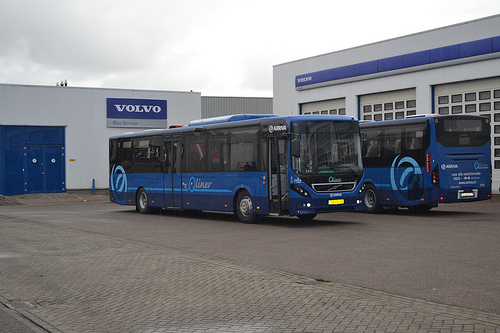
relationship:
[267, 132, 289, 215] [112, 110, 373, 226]
entry door on bus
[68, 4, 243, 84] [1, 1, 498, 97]
clouds in sky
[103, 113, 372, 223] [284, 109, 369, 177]
bus front windshield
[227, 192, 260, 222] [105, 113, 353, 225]
tire on bus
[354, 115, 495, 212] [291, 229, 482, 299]
bus on road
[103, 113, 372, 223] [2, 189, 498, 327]
bus on road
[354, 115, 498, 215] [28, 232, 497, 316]
bus on road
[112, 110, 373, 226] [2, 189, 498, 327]
bus on a road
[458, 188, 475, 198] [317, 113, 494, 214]
plate of bus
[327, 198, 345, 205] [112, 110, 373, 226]
plate of bus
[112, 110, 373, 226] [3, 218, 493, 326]
bus on road